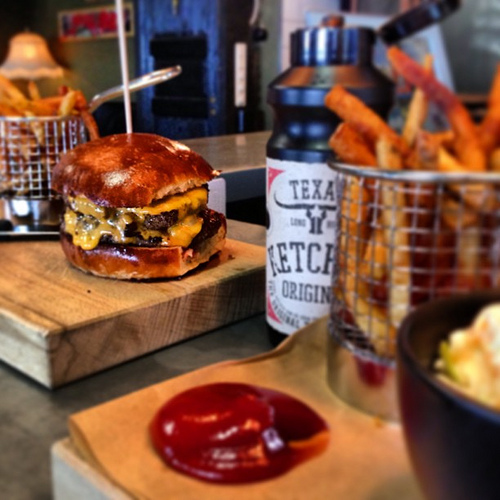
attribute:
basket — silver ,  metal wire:
[3, 112, 80, 229]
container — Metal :
[326, 160, 497, 419]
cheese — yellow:
[61, 179, 225, 263]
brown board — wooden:
[3, 236, 265, 387]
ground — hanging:
[401, 129, 428, 178]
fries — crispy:
[340, 16, 495, 373]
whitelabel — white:
[266, 159, 341, 333]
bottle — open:
[259, 25, 367, 347]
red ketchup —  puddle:
[175, 381, 311, 467]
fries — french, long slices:
[313, 49, 499, 346]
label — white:
[263, 152, 340, 335]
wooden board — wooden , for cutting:
[14, 261, 120, 364]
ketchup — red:
[148, 368, 311, 469]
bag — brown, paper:
[57, 307, 445, 498]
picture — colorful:
[52, 2, 138, 43]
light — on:
[22, 44, 35, 55]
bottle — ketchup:
[264, 48, 391, 358]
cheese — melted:
[168, 229, 192, 249]